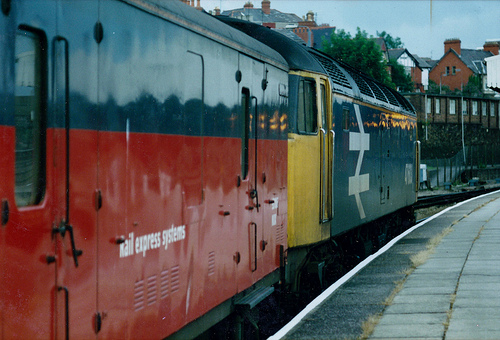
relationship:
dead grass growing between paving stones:
[406, 235, 443, 268] [386, 242, 471, 315]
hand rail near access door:
[53, 33, 79, 267] [0, 0, 100, 339]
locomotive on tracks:
[0, 0, 422, 340] [256, 179, 495, 339]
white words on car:
[119, 222, 189, 262] [0, 0, 290, 340]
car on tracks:
[215, 14, 423, 276] [256, 179, 495, 339]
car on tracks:
[2, 4, 278, 338] [256, 179, 495, 339]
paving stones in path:
[402, 296, 471, 315] [364, 195, 498, 337]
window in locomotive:
[11, 24, 47, 209] [0, 0, 422, 340]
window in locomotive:
[293, 78, 325, 133] [0, 0, 422, 340]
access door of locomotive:
[0, 0, 72, 340] [0, 0, 422, 340]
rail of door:
[319, 127, 332, 222] [315, 77, 334, 221]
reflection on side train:
[0, 88, 420, 338] [28, 29, 433, 279]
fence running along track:
[417, 135, 497, 190] [415, 191, 492, 210]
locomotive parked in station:
[0, 0, 422, 340] [0, 0, 499, 340]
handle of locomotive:
[316, 127, 338, 221] [0, 0, 422, 340]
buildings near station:
[192, 1, 496, 127] [389, 172, 492, 337]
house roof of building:
[429, 47, 494, 75] [426, 35, 498, 92]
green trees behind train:
[317, 26, 415, 93] [26, 27, 414, 338]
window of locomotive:
[11, 27, 47, 209] [0, 0, 422, 340]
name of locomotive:
[117, 219, 190, 261] [4, 5, 415, 337]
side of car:
[5, 0, 285, 325] [0, 0, 290, 340]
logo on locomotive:
[119, 223, 185, 259] [0, 0, 422, 340]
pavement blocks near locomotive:
[278, 189, 498, 339] [0, 0, 422, 340]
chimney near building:
[443, 37, 462, 56] [428, 38, 500, 94]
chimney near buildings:
[257, 0, 271, 16] [182, 0, 334, 48]